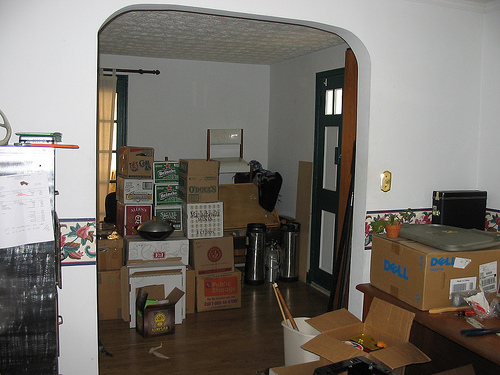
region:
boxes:
[190, 239, 245, 309]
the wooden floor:
[204, 320, 253, 374]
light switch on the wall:
[376, 169, 395, 194]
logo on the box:
[380, 254, 412, 279]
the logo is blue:
[378, 255, 416, 281]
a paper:
[1, 183, 54, 248]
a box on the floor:
[138, 292, 180, 332]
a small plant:
[384, 217, 402, 234]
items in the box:
[352, 330, 383, 349]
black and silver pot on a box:
[127, 205, 180, 247]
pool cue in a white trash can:
[267, 278, 300, 337]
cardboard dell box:
[363, 219, 498, 306]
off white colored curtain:
[94, 63, 116, 238]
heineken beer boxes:
[145, 150, 187, 205]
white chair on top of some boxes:
[196, 105, 259, 190]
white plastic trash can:
[275, 313, 327, 370]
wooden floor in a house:
[88, 267, 344, 374]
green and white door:
[310, 64, 366, 306]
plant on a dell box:
[371, 203, 418, 245]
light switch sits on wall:
[378, 171, 392, 196]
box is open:
[302, 297, 432, 374]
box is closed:
[369, 224, 498, 313]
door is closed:
[306, 67, 356, 300]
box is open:
[130, 281, 183, 333]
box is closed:
[115, 142, 154, 180]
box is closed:
[113, 171, 155, 206]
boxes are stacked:
[95, 146, 275, 335]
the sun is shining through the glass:
[323, 88, 345, 117]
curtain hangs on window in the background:
[98, 71, 123, 221]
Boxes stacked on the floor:
[91, 141, 247, 337]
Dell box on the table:
[371, 226, 497, 318]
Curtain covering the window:
[94, 66, 121, 217]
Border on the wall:
[362, 199, 498, 249]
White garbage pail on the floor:
[281, 313, 331, 368]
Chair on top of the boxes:
[203, 124, 251, 179]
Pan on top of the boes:
[136, 211, 176, 238]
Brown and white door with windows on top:
[307, 66, 349, 289]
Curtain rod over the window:
[95, 61, 167, 78]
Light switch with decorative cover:
[378, 166, 393, 194]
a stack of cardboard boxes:
[111, 134, 227, 316]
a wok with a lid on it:
[120, 214, 193, 262]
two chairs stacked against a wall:
[203, 120, 268, 226]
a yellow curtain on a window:
[96, 61, 166, 238]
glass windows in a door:
[318, 75, 356, 122]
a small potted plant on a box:
[378, 206, 417, 260]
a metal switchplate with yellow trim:
[372, 163, 398, 201]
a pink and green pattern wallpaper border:
[47, 209, 99, 269]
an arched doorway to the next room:
[89, 0, 376, 373]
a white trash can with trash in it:
[262, 267, 341, 369]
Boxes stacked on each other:
[113, 140, 232, 242]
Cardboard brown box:
[179, 155, 221, 203]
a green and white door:
[307, 69, 344, 287]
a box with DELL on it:
[369, 230, 498, 310]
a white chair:
[205, 128, 252, 180]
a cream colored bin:
[281, 313, 318, 363]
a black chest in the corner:
[433, 190, 486, 230]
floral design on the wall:
[59, 218, 96, 265]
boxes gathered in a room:
[98, 143, 275, 336]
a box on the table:
[370, 229, 495, 307]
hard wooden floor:
[101, 283, 324, 371]